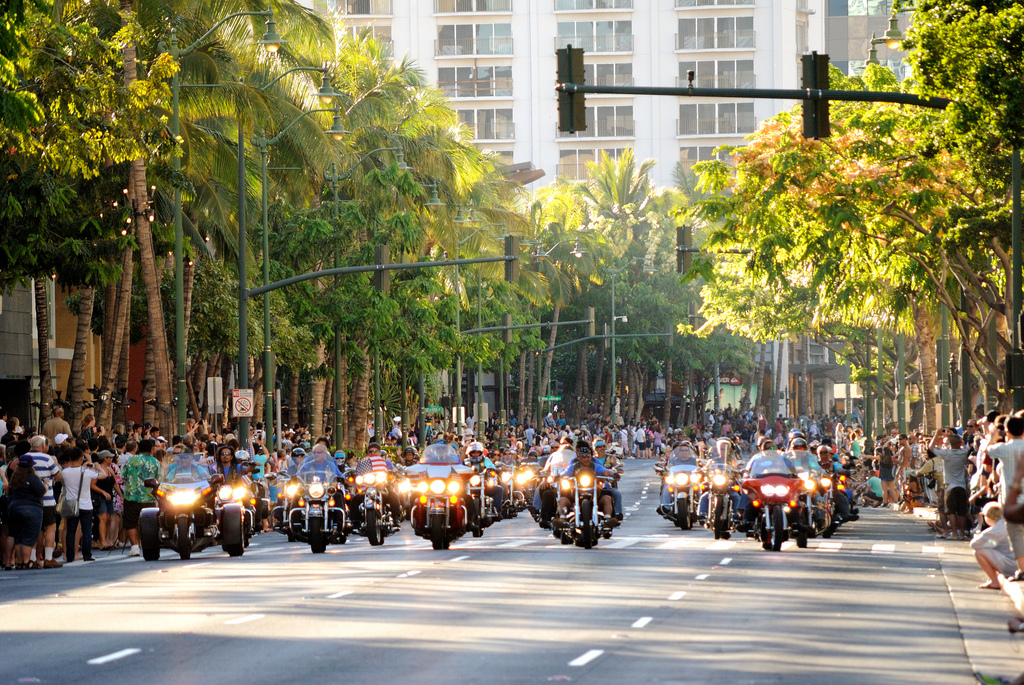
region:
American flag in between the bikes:
[349, 451, 394, 491]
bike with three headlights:
[402, 442, 473, 554]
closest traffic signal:
[548, 42, 997, 154]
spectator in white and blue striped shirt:
[27, 432, 69, 584]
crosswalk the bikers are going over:
[102, 522, 959, 577]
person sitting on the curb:
[952, 496, 1022, 601]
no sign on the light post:
[226, 375, 266, 426]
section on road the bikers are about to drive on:
[10, 531, 969, 681]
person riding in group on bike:
[158, 442, 203, 541]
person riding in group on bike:
[207, 448, 272, 528]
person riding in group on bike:
[272, 454, 359, 562]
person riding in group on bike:
[341, 393, 415, 542]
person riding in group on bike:
[395, 416, 454, 533]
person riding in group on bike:
[452, 436, 533, 509]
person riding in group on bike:
[523, 410, 628, 554]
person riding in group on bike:
[650, 450, 709, 546]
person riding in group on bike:
[749, 434, 823, 537]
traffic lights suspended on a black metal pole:
[550, 44, 959, 146]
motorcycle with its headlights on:
[733, 429, 806, 556]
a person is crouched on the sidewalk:
[961, 503, 1022, 598]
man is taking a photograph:
[54, 443, 112, 565]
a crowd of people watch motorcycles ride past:
[2, 394, 1023, 597]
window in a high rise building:
[675, 15, 701, 53]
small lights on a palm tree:
[88, 177, 162, 245]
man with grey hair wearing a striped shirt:
[13, 432, 71, 572]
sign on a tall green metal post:
[227, 385, 260, 418]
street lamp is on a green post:
[230, 60, 347, 446]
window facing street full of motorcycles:
[456, 107, 476, 141]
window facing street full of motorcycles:
[472, 107, 497, 143]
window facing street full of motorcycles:
[490, 110, 511, 137]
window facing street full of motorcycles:
[435, 66, 458, 98]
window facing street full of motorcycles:
[457, 65, 478, 99]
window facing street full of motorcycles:
[474, 61, 495, 97]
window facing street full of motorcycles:
[492, 61, 513, 99]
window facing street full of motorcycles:
[596, 63, 617, 88]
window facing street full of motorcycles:
[596, 107, 616, 134]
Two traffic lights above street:
[532, 32, 1020, 204]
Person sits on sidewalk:
[965, 499, 1016, 585]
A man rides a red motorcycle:
[741, 439, 814, 548]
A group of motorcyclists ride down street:
[144, 436, 859, 560]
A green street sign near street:
[532, 386, 570, 407]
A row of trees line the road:
[0, 7, 731, 469]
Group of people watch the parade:
[887, 411, 1021, 592]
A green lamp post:
[153, 9, 283, 534]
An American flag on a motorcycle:
[346, 453, 392, 485]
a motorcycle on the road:
[145, 454, 250, 571]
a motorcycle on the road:
[278, 440, 343, 551]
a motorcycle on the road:
[401, 423, 482, 551]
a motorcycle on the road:
[543, 437, 636, 555]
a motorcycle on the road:
[746, 433, 810, 554]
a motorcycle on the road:
[699, 427, 745, 541]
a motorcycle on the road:
[792, 423, 846, 534]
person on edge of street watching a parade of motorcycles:
[10, 451, 55, 569]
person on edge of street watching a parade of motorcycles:
[26, 434, 68, 572]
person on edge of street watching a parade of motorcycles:
[55, 447, 113, 566]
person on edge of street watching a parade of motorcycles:
[92, 447, 122, 555]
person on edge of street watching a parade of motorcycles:
[114, 435, 168, 560]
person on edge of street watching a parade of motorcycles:
[970, 501, 1018, 593]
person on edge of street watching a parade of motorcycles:
[977, 417, 1020, 528]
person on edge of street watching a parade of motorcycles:
[632, 417, 649, 450]